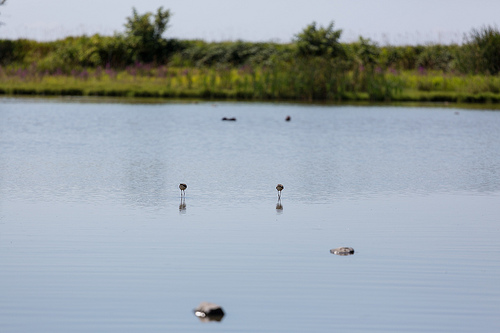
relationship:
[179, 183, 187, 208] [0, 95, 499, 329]
bird sitting in a lake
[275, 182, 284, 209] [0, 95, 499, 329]
bird sitting in a lake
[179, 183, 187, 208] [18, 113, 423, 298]
bird sitting in lake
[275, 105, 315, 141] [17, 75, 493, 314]
bird sitting in lake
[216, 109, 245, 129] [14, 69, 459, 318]
bird sitting in lake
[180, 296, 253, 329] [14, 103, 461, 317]
bird sitting in lake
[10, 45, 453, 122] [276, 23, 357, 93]
bank covered with trees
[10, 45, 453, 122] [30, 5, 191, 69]
bank covered with bushes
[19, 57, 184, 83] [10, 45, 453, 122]
flowers on bank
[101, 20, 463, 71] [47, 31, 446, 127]
bushes on bank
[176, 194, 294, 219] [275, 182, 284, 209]
reflection of bird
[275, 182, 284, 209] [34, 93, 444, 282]
bird on water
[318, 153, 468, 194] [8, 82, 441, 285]
ripples in water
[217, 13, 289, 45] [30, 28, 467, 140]
body above bushes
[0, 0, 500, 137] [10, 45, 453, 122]
background growing along bank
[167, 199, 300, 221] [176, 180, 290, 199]
legs of birds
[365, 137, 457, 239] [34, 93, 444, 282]
body of water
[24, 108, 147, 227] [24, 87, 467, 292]
area of water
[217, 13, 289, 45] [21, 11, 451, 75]
body of skies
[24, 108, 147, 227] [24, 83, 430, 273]
area of water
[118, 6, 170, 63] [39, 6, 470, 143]
tree in background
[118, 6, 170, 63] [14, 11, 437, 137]
tree in background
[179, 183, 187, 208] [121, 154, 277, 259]
bird in water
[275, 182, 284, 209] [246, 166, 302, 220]
bird in water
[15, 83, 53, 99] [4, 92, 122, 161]
rocks in water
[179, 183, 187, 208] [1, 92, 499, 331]
bird in water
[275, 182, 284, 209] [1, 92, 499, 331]
bird in water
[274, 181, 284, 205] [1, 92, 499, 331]
bird in water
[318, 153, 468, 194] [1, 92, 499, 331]
ripples in water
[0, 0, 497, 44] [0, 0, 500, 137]
sky above background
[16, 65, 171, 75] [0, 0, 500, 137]
flowers on background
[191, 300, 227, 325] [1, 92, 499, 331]
bird in water